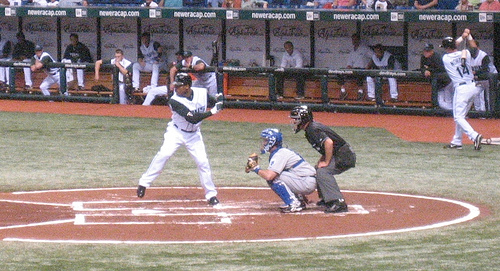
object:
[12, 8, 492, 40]
ledge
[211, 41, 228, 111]
bat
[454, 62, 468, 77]
number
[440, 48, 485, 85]
shirt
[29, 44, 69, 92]
player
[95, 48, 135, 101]
player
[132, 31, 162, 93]
player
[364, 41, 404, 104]
player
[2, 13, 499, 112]
dugout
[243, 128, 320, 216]
catcher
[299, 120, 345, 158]
shirt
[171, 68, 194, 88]
hat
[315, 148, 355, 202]
pants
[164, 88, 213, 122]
top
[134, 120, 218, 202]
pants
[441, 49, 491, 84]
top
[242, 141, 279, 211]
mit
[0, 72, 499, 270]
field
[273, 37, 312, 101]
man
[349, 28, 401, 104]
man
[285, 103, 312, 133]
helmet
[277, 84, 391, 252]
man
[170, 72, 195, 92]
helmet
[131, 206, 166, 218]
home plate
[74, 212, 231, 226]
batter box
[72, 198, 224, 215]
batter box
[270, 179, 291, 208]
safety pad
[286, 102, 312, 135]
safety gear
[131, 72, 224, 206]
man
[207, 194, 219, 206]
footwear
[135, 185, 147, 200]
footwear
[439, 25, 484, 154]
male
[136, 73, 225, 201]
baseball player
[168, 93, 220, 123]
sleeves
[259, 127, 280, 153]
helmet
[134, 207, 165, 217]
baseball plate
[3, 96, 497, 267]
ground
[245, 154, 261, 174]
glove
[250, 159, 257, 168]
hand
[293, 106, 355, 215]
umpire